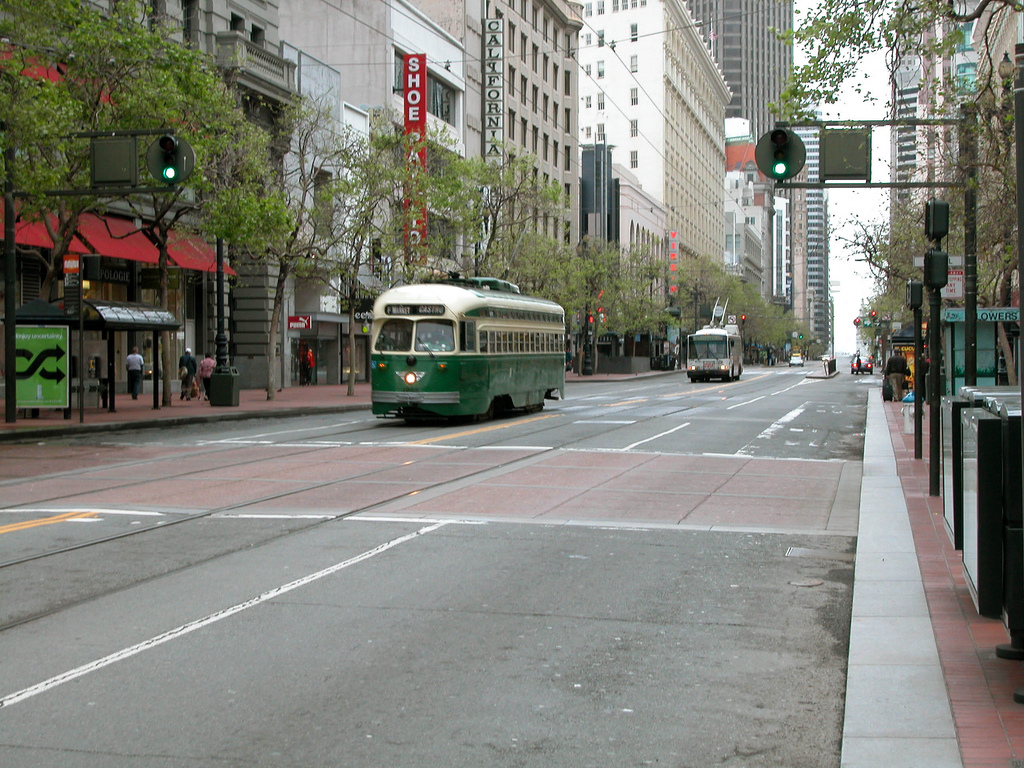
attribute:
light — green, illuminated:
[161, 165, 177, 179]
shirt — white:
[122, 355, 149, 369]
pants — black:
[127, 373, 145, 395]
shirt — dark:
[179, 355, 192, 377]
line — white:
[0, 522, 454, 710]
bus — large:
[680, 327, 750, 386]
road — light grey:
[1, 360, 872, 758]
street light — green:
[775, 159, 784, 173]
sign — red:
[401, 49, 425, 266]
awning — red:
[3, 208, 235, 276]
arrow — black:
[10, 347, 67, 378]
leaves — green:
[0, 0, 292, 256]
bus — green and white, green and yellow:
[366, 273, 570, 423]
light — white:
[405, 368, 416, 388]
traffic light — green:
[751, 122, 804, 187]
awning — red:
[0, 202, 242, 280]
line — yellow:
[3, 509, 94, 536]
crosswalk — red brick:
[4, 433, 862, 544]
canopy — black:
[62, 303, 179, 330]